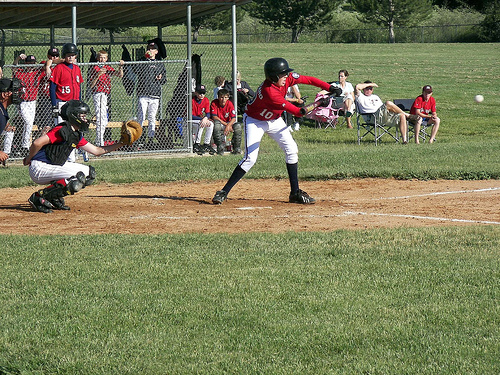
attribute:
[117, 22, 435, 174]
people — these 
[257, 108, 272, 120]
number — 10  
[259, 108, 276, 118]
10 — jersey number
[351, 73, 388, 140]
people — Seated 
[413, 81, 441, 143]
people — Seated 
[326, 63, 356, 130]
people — Seated 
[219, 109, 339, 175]
pant — boy's, white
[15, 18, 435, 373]
background — Filled 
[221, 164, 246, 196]
socks — boy's, black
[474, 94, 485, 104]
ball — Flying 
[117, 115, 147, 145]
catcher's mitt — Brown 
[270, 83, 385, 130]
batting helmet —  black batting 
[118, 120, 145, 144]
glove —  out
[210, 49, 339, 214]
boy — Swinging 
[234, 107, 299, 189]
pants —  boy's 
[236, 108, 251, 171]
stripe — black 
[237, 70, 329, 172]
uniform — red, white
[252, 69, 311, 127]
shirt — red, boy's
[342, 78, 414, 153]
person — Seated 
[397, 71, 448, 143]
person — Seated 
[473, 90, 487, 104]
baseball — white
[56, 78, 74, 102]
numbers — white 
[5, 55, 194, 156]
fence — metal 